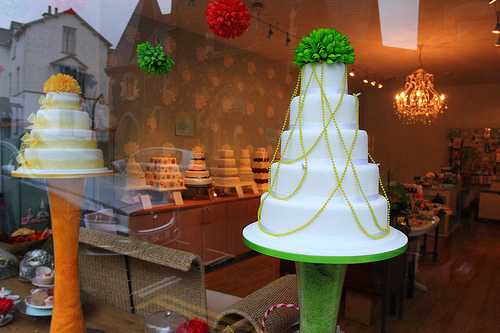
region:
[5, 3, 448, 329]
Cakes in a window display.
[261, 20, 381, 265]
The cake is topped with a green decoration.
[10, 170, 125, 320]
The pedestal is orange.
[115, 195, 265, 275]
A long wooden cabinet.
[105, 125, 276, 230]
A row of cakes are on top of the cabinet.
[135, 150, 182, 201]
The cake is square.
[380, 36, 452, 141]
A chandelier is hanging from the ceiling.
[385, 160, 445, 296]
The white table is covered in objects.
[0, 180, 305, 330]
A sofa is behind the window.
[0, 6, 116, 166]
The reflection of a building.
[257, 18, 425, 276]
Five tier cake with green bow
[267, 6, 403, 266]
Five tier cake with green decorative beads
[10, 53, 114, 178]
Four tier cake with yellow bows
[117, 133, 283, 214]
Beautiful cakes sitting on counter top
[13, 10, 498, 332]
Cake shop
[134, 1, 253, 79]
Green and red bow in store window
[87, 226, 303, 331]
Beige and white bench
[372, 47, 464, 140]
Chandelier hanging from the ceiling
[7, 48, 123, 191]
White cake topped with yellow bow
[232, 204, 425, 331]
Green and white table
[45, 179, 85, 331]
Base of orange pedestal display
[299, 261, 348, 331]
Base of green pedestal display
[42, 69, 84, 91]
Orange adornment on top of 4-tier white cake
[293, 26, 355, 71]
Green adornment on top of 5-tier white cake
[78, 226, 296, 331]
Chair just inside the window behind the cakes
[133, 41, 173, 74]
Green adornment in the air between the two large cakes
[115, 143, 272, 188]
Entire row of cakes inside the establishment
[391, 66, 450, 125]
Lit chandelier hanging from the ceiling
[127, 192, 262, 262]
Brown case the cakes inside are sitting on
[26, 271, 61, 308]
Cupcakes on display to the left of the orange pedestal base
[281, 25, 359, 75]
Green bow on top of a cake.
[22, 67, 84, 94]
Yellow bow on top of a cake.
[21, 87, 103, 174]
Yellow ribbon on the cake.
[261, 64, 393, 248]
Gold bead strands on the cake.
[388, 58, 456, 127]
Chandelier hanging from the ceiling.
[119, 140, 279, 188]
Cakes against a wall.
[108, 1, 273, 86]
Bows hanging from the wall.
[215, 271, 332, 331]
Arm of a chair.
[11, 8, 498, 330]
Picture was taken at a bakery.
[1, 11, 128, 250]
Reflection of a house in the background.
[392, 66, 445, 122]
The chandelier is turned on.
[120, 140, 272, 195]
There are many cakes on display.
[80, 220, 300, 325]
There is a place to sit inside.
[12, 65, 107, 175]
The bows match the decoration on top.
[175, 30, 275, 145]
There is wallpaper in the shop.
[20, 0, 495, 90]
Green, red and yellow decorations.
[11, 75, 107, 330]
The cake is on a display platform.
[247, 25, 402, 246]
There are beads on the cake.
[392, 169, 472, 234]
More treats on display.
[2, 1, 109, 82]
There is a reflection in the window.